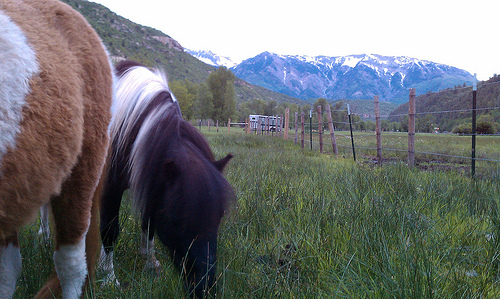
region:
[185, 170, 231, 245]
part f a head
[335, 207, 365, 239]
part of a grass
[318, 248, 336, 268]
part of a grass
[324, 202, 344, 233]
part of a grass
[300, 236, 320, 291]
part of a grass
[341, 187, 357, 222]
part of a grass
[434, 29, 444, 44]
part of a cloud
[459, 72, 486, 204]
This is a pole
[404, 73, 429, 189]
This is a pole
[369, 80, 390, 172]
This is a pole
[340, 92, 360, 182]
This is a pole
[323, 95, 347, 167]
This is a pole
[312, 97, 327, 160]
This is a pole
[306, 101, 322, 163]
This is a pole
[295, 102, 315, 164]
This is a pole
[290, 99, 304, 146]
This is a pole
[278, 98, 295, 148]
This is a pole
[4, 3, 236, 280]
the horses are grazing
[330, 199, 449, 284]
the grass is tall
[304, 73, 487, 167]
fence in the field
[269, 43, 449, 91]
snow on the mountain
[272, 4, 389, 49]
the sky is bright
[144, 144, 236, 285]
head of the horse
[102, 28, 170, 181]
mane of the horse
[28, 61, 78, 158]
fur of the horse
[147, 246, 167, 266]
hoof of the horse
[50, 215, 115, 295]
leg of the horse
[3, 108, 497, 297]
green grass on the ground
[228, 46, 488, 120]
mountains in the distance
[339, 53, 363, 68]
white snow on top of the mountain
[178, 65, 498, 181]
fence along the grass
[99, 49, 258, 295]
pony grazing in the grass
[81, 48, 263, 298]
black and white pony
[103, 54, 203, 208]
long white hair on the neck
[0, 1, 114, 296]
brown and white animal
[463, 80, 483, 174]
black post on the fence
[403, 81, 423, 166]
brown post on the fence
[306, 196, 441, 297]
the grasess are tall in lenght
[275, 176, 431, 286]
the grasses are green in color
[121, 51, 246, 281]
the horse is black and white in color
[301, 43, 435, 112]
hills are seen far away from the view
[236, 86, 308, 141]
a house is in the valley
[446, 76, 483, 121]
the hills have green bushes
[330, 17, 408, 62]
sky is clear in color